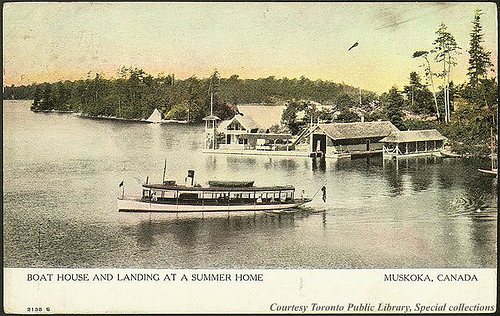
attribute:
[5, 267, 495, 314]
black lettering —  black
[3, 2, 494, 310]
card —  white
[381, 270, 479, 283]
writing — black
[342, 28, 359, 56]
bird — flying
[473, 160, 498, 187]
boat —  another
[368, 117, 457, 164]
dock — for boat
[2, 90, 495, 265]
water — calm,  calm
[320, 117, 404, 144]
roof —  boathouse's 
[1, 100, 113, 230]
river — wide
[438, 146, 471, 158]
boat —  Small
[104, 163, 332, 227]
boat — long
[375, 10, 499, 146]
trees —  More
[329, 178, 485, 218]
water —  rippling